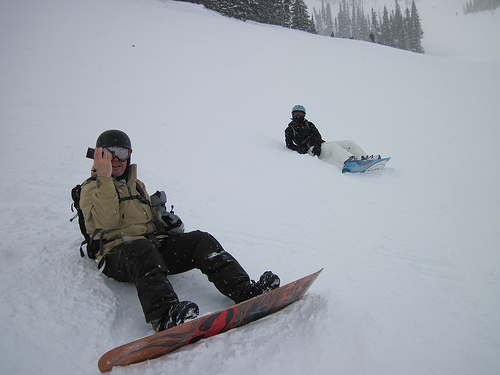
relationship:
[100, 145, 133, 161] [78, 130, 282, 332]
goggles on man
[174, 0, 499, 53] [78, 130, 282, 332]
trees behind man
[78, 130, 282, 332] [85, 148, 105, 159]
man holding h phone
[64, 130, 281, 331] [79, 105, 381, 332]
man sitting together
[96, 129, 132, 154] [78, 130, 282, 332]
helmet on man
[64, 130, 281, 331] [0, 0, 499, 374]
man sitting on snow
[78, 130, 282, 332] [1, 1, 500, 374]
man sitting for a picture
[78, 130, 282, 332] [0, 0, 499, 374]
man sitting on snow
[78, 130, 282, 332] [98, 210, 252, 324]
man wearing black pants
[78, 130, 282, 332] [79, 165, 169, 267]
man wearing a jacket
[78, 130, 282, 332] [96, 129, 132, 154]
man wearing a helmet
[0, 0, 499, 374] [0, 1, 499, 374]
snow on ground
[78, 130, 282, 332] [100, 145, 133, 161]
man wearing goggles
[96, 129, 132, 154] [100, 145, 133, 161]
helmet and goggles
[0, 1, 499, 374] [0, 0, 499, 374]
slope topped with snow